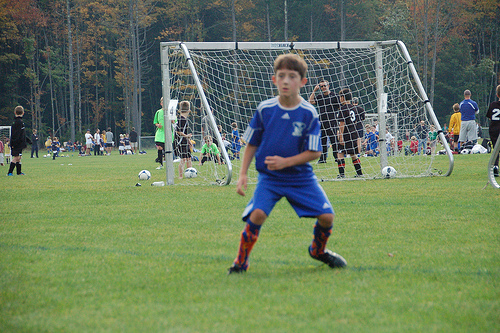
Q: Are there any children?
A: Yes, there are children.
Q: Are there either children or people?
A: Yes, there are children.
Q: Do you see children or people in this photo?
A: Yes, there are children.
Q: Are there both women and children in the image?
A: No, there are children but no women.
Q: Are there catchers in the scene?
A: No, there are no catchers.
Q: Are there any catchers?
A: No, there are no catchers.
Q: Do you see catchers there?
A: No, there are no catchers.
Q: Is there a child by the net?
A: Yes, there are children by the net.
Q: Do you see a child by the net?
A: Yes, there are children by the net.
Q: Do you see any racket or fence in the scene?
A: No, there are no fences or rackets.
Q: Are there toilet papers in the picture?
A: No, there are no toilet papers.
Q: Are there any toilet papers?
A: No, there are no toilet papers.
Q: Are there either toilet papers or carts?
A: No, there are no toilet papers or carts.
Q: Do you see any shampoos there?
A: No, there are no shampoos.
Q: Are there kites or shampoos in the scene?
A: No, there are no shampoos or kites.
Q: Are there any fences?
A: No, there are no fences.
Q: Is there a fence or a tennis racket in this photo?
A: No, there are no fences or rackets.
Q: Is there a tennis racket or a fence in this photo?
A: No, there are no fences or rackets.